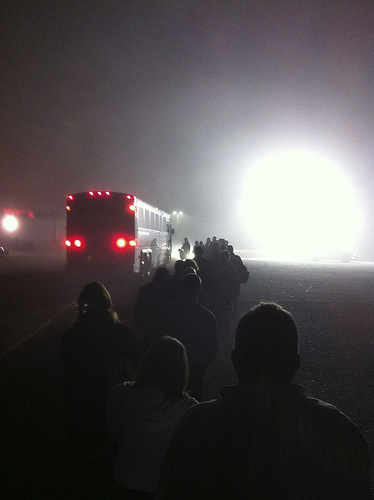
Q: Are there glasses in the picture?
A: No, there are no glasses.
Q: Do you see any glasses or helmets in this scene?
A: No, there are no glasses or helmets.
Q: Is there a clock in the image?
A: No, there are no clocks.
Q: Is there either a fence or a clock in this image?
A: No, there are no clocks or fences.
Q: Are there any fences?
A: No, there are no fences.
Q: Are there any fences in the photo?
A: No, there are no fences.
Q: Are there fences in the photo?
A: No, there are no fences.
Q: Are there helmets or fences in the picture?
A: No, there are no fences or helmets.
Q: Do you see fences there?
A: No, there are no fences.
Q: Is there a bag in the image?
A: No, there are no bags.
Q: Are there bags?
A: No, there are no bags.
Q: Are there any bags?
A: No, there are no bags.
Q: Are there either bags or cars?
A: No, there are no bags or cars.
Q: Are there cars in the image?
A: No, there are no cars.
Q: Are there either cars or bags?
A: No, there are no cars or bags.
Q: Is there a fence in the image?
A: No, there are no fences.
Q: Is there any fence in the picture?
A: No, there are no fences.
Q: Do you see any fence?
A: No, there are no fences.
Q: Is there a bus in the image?
A: Yes, there is a bus.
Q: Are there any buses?
A: Yes, there is a bus.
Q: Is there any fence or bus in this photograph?
A: Yes, there is a bus.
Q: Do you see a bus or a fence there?
A: Yes, there is a bus.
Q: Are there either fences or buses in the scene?
A: Yes, there is a bus.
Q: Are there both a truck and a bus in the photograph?
A: No, there is a bus but no trucks.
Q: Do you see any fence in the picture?
A: No, there are no fences.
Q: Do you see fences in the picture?
A: No, there are no fences.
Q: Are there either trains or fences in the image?
A: No, there are no fences or trains.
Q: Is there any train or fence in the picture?
A: No, there are no fences or trains.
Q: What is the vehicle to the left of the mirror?
A: The vehicle is a bus.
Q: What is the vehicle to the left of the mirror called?
A: The vehicle is a bus.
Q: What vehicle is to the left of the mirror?
A: The vehicle is a bus.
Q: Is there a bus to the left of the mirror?
A: Yes, there is a bus to the left of the mirror.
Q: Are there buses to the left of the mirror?
A: Yes, there is a bus to the left of the mirror.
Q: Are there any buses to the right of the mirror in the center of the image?
A: No, the bus is to the left of the mirror.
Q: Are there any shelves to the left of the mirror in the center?
A: No, there is a bus to the left of the mirror.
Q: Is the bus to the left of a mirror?
A: Yes, the bus is to the left of a mirror.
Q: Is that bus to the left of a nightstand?
A: No, the bus is to the left of a mirror.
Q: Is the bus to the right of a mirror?
A: No, the bus is to the left of a mirror.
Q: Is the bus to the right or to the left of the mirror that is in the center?
A: The bus is to the left of the mirror.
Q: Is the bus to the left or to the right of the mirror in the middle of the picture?
A: The bus is to the left of the mirror.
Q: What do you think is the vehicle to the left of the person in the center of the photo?
A: The vehicle is a bus.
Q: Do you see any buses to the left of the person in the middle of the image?
A: Yes, there is a bus to the left of the person.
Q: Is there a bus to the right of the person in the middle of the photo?
A: No, the bus is to the left of the person.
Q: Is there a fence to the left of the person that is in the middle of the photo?
A: No, there is a bus to the left of the person.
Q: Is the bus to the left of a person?
A: Yes, the bus is to the left of a person.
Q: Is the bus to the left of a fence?
A: No, the bus is to the left of a person.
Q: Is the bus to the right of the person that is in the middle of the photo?
A: No, the bus is to the left of the person.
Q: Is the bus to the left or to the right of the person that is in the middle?
A: The bus is to the left of the person.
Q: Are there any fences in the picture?
A: No, there are no fences.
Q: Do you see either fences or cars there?
A: No, there are no fences or cars.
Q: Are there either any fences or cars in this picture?
A: No, there are no fences or cars.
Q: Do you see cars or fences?
A: No, there are no fences or cars.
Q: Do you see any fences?
A: No, there are no fences.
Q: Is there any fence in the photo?
A: No, there are no fences.